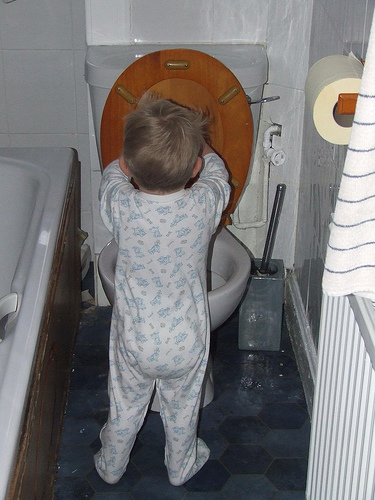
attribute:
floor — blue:
[50, 259, 312, 498]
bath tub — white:
[0, 147, 87, 497]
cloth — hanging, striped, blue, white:
[322, 7, 375, 302]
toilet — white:
[84, 42, 280, 413]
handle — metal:
[244, 94, 280, 107]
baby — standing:
[94, 99, 231, 488]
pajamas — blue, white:
[93, 153, 232, 487]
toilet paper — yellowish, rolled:
[305, 50, 365, 145]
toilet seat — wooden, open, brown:
[100, 47, 252, 226]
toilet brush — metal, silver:
[254, 185, 285, 277]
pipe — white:
[233, 124, 286, 230]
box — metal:
[237, 257, 285, 351]